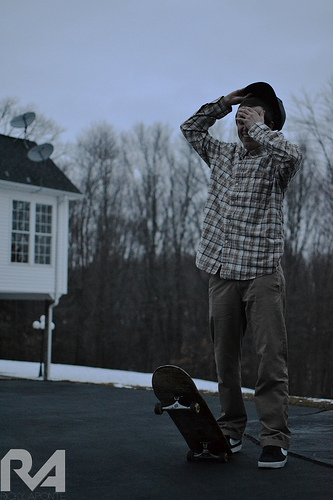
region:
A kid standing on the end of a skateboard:
[144, 76, 312, 475]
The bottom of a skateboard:
[147, 358, 237, 471]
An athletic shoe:
[251, 435, 294, 476]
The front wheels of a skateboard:
[148, 397, 205, 421]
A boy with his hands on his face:
[219, 75, 289, 164]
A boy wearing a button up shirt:
[175, 79, 307, 283]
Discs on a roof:
[6, 106, 58, 168]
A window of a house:
[5, 196, 57, 269]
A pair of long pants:
[201, 252, 298, 453]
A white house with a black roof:
[0, 123, 88, 385]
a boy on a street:
[83, 29, 332, 464]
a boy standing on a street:
[90, 72, 321, 498]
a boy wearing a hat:
[84, 55, 328, 279]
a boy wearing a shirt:
[126, 62, 332, 306]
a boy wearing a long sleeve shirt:
[120, 60, 332, 349]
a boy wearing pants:
[113, 53, 313, 454]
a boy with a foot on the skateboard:
[103, 58, 321, 473]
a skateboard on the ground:
[91, 58, 325, 493]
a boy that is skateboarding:
[91, 83, 332, 494]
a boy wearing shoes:
[90, 70, 332, 475]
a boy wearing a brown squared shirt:
[161, 67, 314, 292]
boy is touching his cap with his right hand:
[172, 71, 313, 207]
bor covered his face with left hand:
[173, 69, 308, 199]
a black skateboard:
[142, 355, 238, 468]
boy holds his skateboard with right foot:
[139, 67, 304, 487]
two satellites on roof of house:
[3, 101, 58, 182]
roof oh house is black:
[0, 133, 92, 197]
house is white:
[0, 126, 89, 377]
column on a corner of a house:
[27, 271, 70, 382]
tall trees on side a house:
[69, 107, 186, 363]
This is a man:
[175, 80, 309, 477]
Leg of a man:
[246, 274, 296, 481]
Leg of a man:
[196, 260, 247, 473]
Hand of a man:
[178, 79, 246, 162]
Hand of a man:
[236, 104, 317, 187]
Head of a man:
[216, 69, 283, 162]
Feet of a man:
[254, 425, 296, 479]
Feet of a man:
[208, 411, 245, 469]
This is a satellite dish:
[8, 106, 39, 134]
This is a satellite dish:
[25, 137, 60, 166]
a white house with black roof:
[1, 125, 89, 382]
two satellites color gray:
[4, 105, 61, 169]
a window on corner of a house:
[5, 193, 59, 272]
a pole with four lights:
[26, 306, 58, 379]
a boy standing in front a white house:
[2, 71, 310, 475]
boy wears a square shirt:
[172, 63, 314, 292]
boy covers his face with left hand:
[167, 69, 312, 205]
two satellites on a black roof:
[0, 105, 84, 198]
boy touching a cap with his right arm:
[171, 74, 320, 486]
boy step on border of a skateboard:
[144, 75, 314, 481]